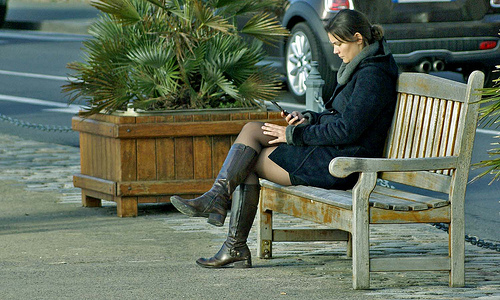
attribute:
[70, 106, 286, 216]
box — brown, wooden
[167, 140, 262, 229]
boot — brown, black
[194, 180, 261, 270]
boot — black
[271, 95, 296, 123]
phone — white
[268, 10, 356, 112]
tire — vehicle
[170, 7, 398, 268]
lady — light skinned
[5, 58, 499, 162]
lines — white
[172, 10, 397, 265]
woman — wooden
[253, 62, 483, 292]
bench — gray, wooden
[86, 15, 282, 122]
plant — green, palm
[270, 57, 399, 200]
coat — black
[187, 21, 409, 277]
women — sitting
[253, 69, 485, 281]
chair — old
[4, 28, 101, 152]
roadway — paved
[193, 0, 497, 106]
vehicle — colored, dark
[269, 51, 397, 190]
coat — blue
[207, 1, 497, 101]
vehicle — black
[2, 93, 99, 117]
line — white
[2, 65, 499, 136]
line — white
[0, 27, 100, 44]
line — white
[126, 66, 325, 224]
woman — sitting